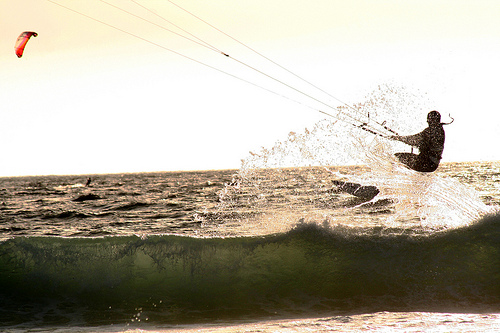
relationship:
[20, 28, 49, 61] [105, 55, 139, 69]
kite in sky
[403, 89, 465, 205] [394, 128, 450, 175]
man wearing costume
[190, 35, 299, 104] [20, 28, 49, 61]
cord connected to kite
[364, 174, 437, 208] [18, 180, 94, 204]
splash of water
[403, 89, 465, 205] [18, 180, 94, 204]
man in water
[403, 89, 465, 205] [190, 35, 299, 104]
man holding cord